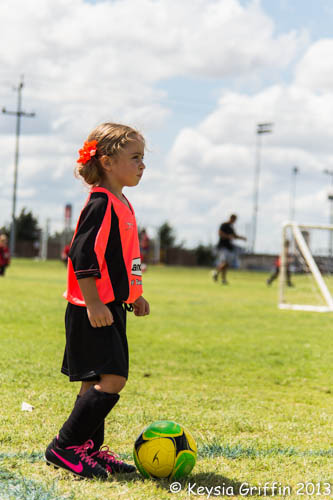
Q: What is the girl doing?
A: Playing football.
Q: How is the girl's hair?
A: Pretty.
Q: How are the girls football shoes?
A: Pink.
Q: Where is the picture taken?
A: Field.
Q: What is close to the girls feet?
A: A football.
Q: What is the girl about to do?
A: Kick the ball.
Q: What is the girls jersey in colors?
A: Orange and black.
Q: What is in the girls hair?
A: A flower.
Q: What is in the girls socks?
A: Shin pads.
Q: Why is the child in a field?
A: To play soccer.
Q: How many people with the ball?
A: One.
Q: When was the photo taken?
A: Day time.